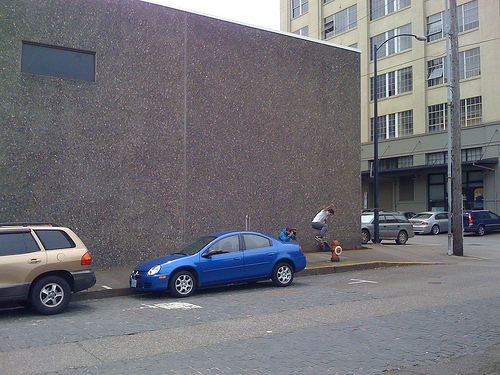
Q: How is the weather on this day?
A: It is cloudy.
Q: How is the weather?
A: It is cloudy.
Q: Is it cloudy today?
A: Yes, it is cloudy.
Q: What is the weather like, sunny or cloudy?
A: It is cloudy.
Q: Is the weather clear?
A: No, it is cloudy.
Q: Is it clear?
A: No, it is cloudy.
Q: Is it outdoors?
A: Yes, it is outdoors.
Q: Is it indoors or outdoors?
A: It is outdoors.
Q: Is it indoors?
A: No, it is outdoors.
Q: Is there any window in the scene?
A: Yes, there is a window.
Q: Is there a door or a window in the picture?
A: Yes, there is a window.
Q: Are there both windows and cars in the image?
A: Yes, there are both a window and a car.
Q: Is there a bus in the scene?
A: No, there are no buses.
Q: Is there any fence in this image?
A: No, there are no fences.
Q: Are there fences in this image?
A: No, there are no fences.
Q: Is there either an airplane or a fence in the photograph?
A: No, there are no fences or airplanes.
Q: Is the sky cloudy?
A: Yes, the sky is cloudy.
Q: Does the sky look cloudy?
A: Yes, the sky is cloudy.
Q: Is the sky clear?
A: No, the sky is cloudy.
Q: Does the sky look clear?
A: No, the sky is cloudy.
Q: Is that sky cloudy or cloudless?
A: The sky is cloudy.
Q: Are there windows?
A: Yes, there is a window.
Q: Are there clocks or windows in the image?
A: Yes, there is a window.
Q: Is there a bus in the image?
A: No, there are no buses.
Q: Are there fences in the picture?
A: No, there are no fences.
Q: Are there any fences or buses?
A: No, there are no fences or buses.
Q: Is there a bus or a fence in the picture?
A: No, there are no fences or buses.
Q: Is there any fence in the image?
A: No, there are no fences.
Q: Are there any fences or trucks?
A: No, there are no fences or trucks.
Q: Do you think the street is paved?
A: Yes, the street is paved.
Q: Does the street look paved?
A: Yes, the street is paved.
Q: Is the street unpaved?
A: No, the street is paved.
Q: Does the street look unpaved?
A: No, the street is paved.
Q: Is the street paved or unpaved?
A: The street is paved.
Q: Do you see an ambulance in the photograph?
A: No, there are no ambulances.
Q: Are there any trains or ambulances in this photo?
A: No, there are no ambulances or trains.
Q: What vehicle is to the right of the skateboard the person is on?
A: The vehicle is a car.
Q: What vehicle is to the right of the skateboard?
A: The vehicle is a car.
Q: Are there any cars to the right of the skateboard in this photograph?
A: Yes, there is a car to the right of the skateboard.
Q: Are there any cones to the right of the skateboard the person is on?
A: No, there is a car to the right of the skateboard.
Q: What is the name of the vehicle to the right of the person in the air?
A: The vehicle is a car.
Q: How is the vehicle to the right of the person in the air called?
A: The vehicle is a car.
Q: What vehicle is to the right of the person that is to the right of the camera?
A: The vehicle is a car.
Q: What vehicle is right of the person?
A: The vehicle is a car.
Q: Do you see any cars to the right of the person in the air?
A: Yes, there is a car to the right of the person.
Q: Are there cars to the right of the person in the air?
A: Yes, there is a car to the right of the person.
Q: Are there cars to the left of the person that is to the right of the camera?
A: No, the car is to the right of the person.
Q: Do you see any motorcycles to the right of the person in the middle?
A: No, there is a car to the right of the person.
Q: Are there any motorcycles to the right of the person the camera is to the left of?
A: No, there is a car to the right of the person.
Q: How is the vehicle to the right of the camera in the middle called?
A: The vehicle is a car.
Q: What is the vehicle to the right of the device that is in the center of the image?
A: The vehicle is a car.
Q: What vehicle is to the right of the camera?
A: The vehicle is a car.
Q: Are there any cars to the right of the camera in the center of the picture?
A: Yes, there is a car to the right of the camera.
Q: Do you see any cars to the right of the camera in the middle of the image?
A: Yes, there is a car to the right of the camera.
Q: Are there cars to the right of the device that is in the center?
A: Yes, there is a car to the right of the camera.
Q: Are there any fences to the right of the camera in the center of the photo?
A: No, there is a car to the right of the camera.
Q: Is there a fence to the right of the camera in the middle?
A: No, there is a car to the right of the camera.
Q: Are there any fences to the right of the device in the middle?
A: No, there is a car to the right of the camera.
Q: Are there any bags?
A: No, there are no bags.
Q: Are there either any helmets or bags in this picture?
A: No, there are no bags or helmets.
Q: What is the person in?
A: The person is in the air.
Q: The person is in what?
A: The person is in the air.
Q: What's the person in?
A: The person is in the air.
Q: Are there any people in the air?
A: Yes, there is a person in the air.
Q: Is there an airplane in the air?
A: No, there is a person in the air.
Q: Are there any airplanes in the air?
A: No, there is a person in the air.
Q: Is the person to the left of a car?
A: Yes, the person is to the left of a car.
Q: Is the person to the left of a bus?
A: No, the person is to the left of a car.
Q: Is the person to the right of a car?
A: No, the person is to the left of a car.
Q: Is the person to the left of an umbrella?
A: No, the person is to the left of a car.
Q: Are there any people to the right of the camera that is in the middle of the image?
A: Yes, there is a person to the right of the camera.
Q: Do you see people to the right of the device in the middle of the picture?
A: Yes, there is a person to the right of the camera.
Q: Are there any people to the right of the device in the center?
A: Yes, there is a person to the right of the camera.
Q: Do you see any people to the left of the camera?
A: No, the person is to the right of the camera.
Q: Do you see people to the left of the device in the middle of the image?
A: No, the person is to the right of the camera.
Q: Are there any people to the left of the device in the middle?
A: No, the person is to the right of the camera.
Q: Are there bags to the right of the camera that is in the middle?
A: No, there is a person to the right of the camera.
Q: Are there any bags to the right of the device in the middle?
A: No, there is a person to the right of the camera.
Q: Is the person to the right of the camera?
A: Yes, the person is to the right of the camera.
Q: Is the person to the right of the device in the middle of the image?
A: Yes, the person is to the right of the camera.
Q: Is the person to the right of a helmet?
A: No, the person is to the right of the camera.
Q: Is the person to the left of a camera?
A: No, the person is to the right of a camera.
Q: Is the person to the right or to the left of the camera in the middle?
A: The person is to the right of the camera.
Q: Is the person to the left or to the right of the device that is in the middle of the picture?
A: The person is to the right of the camera.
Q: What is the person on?
A: The person is on the skateboard.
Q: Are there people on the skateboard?
A: Yes, there is a person on the skateboard.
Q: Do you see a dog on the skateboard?
A: No, there is a person on the skateboard.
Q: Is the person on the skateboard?
A: Yes, the person is on the skateboard.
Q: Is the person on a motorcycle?
A: No, the person is on the skateboard.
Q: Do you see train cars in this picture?
A: No, there are no train cars.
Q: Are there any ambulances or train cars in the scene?
A: No, there are no train cars or ambulances.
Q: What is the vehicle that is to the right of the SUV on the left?
A: The vehicle is a car.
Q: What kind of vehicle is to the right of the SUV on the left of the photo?
A: The vehicle is a car.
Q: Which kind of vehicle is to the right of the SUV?
A: The vehicle is a car.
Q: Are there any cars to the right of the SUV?
A: Yes, there is a car to the right of the SUV.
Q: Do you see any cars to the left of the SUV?
A: No, the car is to the right of the SUV.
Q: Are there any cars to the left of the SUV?
A: No, the car is to the right of the SUV.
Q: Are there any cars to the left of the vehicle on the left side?
A: No, the car is to the right of the SUV.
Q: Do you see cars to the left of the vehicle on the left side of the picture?
A: No, the car is to the right of the SUV.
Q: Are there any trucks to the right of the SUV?
A: No, there is a car to the right of the SUV.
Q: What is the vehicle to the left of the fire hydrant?
A: The vehicle is a car.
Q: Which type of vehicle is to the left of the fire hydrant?
A: The vehicle is a car.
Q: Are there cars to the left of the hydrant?
A: Yes, there is a car to the left of the hydrant.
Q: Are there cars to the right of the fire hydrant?
A: No, the car is to the left of the fire hydrant.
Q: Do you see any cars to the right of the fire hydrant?
A: No, the car is to the left of the fire hydrant.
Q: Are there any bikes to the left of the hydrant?
A: No, there is a car to the left of the hydrant.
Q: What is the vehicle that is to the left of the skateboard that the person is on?
A: The vehicle is a car.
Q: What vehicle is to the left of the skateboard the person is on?
A: The vehicle is a car.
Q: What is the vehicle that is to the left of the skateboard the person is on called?
A: The vehicle is a car.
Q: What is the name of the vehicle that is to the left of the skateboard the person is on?
A: The vehicle is a car.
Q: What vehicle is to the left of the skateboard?
A: The vehicle is a car.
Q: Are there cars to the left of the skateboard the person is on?
A: Yes, there is a car to the left of the skateboard.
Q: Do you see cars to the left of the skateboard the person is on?
A: Yes, there is a car to the left of the skateboard.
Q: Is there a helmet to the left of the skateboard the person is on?
A: No, there is a car to the left of the skateboard.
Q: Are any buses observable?
A: No, there are no buses.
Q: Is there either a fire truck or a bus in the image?
A: No, there are no buses or fire trucks.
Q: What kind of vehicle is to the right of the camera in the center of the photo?
A: The vehicle is a car.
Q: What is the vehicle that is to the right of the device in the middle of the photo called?
A: The vehicle is a car.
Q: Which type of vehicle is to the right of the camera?
A: The vehicle is a car.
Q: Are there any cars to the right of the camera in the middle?
A: Yes, there is a car to the right of the camera.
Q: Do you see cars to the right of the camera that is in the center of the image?
A: Yes, there is a car to the right of the camera.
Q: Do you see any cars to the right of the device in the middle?
A: Yes, there is a car to the right of the camera.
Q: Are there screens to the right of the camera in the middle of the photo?
A: No, there is a car to the right of the camera.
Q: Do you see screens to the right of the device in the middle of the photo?
A: No, there is a car to the right of the camera.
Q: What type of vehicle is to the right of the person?
A: The vehicle is a car.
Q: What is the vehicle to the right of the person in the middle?
A: The vehicle is a car.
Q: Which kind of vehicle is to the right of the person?
A: The vehicle is a car.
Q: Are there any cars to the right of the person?
A: Yes, there is a car to the right of the person.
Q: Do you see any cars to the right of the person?
A: Yes, there is a car to the right of the person.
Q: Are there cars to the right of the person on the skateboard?
A: Yes, there is a car to the right of the person.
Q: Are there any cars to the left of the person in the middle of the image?
A: No, the car is to the right of the person.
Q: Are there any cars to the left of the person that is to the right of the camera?
A: No, the car is to the right of the person.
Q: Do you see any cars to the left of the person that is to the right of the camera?
A: No, the car is to the right of the person.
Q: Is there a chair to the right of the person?
A: No, there is a car to the right of the person.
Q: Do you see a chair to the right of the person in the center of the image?
A: No, there is a car to the right of the person.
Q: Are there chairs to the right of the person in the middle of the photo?
A: No, there is a car to the right of the person.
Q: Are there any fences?
A: No, there are no fences.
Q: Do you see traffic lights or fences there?
A: No, there are no fences or traffic lights.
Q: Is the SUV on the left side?
A: Yes, the SUV is on the left of the image.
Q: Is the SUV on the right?
A: No, the SUV is on the left of the image.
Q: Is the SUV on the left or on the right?
A: The SUV is on the left of the image.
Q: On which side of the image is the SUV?
A: The SUV is on the left of the image.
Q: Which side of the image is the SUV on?
A: The SUV is on the left of the image.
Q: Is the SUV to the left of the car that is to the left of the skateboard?
A: Yes, the SUV is to the left of the car.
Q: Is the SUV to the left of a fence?
A: No, the SUV is to the left of the car.